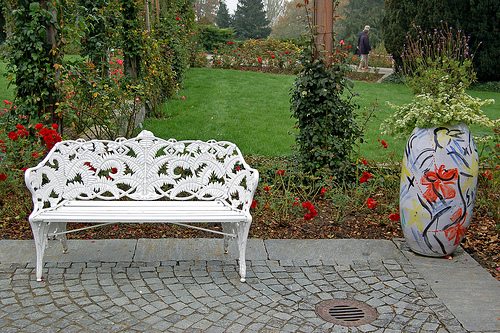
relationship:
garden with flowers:
[1, 10, 498, 236] [2, 36, 499, 222]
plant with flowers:
[382, 15, 496, 124] [390, 19, 472, 88]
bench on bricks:
[23, 127, 261, 281] [244, 297, 260, 307]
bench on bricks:
[23, 127, 261, 281] [149, 281, 165, 292]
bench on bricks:
[23, 127, 261, 281] [38, 302, 59, 312]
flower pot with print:
[399, 121, 478, 257] [411, 153, 465, 253]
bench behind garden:
[24, 129, 259, 283] [0, 51, 494, 243]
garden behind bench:
[1, 10, 498, 236] [23, 127, 261, 281]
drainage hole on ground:
[312, 297, 378, 326] [0, 54, 499, 331]